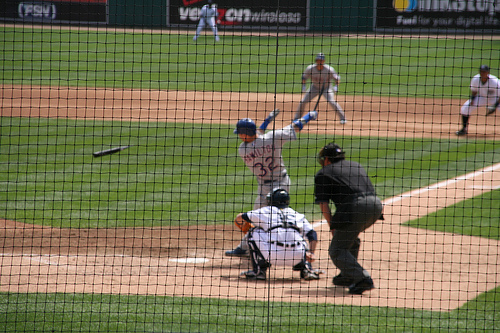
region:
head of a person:
[222, 105, 266, 143]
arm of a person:
[266, 101, 301, 155]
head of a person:
[253, 173, 294, 223]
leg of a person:
[239, 226, 284, 298]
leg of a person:
[286, 249, 317, 286]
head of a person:
[307, 112, 362, 164]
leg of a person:
[299, 169, 351, 257]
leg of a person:
[323, 215, 367, 295]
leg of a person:
[316, 82, 361, 124]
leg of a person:
[290, 81, 320, 123]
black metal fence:
[1, 1, 496, 331]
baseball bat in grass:
[85, 132, 150, 167]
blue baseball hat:
[221, 110, 263, 138]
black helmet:
[252, 185, 297, 210]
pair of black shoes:
[329, 263, 381, 298]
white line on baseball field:
[387, 164, 487, 213]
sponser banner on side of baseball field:
[165, 0, 316, 36]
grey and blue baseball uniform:
[233, 136, 300, 211]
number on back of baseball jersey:
[249, 151, 289, 183]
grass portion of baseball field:
[4, 25, 499, 112]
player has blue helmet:
[233, 121, 262, 136]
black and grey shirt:
[235, 145, 291, 182]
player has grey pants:
[253, 176, 296, 208]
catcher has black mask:
[255, 184, 291, 216]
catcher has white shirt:
[262, 206, 313, 254]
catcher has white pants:
[260, 241, 309, 273]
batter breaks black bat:
[94, 144, 167, 177]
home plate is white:
[178, 236, 205, 283]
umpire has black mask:
[310, 141, 350, 173]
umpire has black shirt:
[320, 156, 362, 201]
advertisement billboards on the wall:
[5, 1, 499, 33]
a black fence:
[3, 3, 486, 331]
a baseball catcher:
[237, 189, 318, 273]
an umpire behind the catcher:
[308, 140, 387, 282]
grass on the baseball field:
[20, 115, 182, 200]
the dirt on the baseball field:
[13, 231, 230, 284]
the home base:
[170, 250, 217, 265]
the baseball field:
[20, 15, 495, 320]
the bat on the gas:
[89, 136, 131, 156]